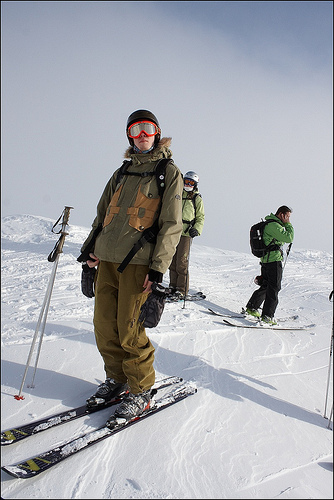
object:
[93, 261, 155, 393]
jeans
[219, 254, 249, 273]
ground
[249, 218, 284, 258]
backpack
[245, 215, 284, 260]
backpack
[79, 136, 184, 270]
jacket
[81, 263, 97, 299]
gloves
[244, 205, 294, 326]
man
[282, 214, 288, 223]
hand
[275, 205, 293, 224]
head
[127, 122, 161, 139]
eyewear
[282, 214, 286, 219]
cell phone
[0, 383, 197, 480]
skis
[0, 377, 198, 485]
skis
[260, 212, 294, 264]
coat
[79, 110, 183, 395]
man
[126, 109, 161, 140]
helmet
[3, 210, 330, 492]
mountain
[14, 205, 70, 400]
skier's poles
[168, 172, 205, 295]
man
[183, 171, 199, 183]
helmet